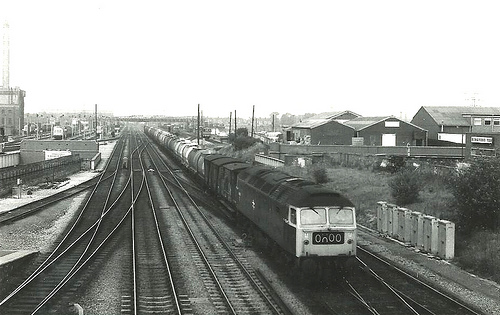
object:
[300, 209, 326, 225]
windows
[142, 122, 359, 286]
train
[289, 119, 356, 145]
storage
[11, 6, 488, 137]
backgorund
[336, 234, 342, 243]
letter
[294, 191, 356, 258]
front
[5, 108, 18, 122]
brick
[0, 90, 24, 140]
building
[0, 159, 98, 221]
platform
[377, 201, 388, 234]
boxes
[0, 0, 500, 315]
picture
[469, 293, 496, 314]
gravel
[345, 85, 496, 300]
side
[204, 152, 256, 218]
cars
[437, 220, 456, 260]
object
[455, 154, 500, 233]
bush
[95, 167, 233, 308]
rail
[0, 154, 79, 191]
fence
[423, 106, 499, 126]
roof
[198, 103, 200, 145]
pole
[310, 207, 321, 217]
wipers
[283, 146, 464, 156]
fence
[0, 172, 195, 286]
ground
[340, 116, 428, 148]
buildings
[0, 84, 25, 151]
tower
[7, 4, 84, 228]
side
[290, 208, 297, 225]
window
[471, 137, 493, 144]
sign